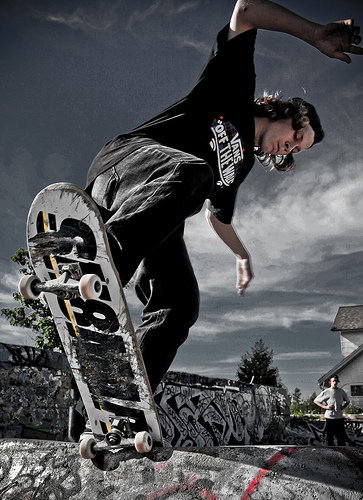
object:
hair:
[254, 87, 325, 173]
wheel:
[78, 273, 102, 299]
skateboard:
[18, 182, 166, 461]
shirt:
[313, 387, 350, 419]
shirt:
[83, 39, 256, 225]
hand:
[235, 255, 252, 296]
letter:
[60, 340, 130, 374]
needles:
[249, 346, 273, 358]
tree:
[237, 335, 296, 387]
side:
[8, 362, 280, 451]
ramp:
[15, 401, 361, 487]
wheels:
[19, 275, 42, 300]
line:
[247, 442, 283, 494]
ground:
[0, 437, 363, 488]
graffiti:
[166, 382, 274, 439]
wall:
[24, 340, 329, 446]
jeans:
[325, 418, 347, 448]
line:
[57, 287, 91, 350]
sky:
[17, 21, 201, 111]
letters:
[209, 120, 244, 188]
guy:
[82, 0, 363, 435]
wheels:
[79, 437, 97, 460]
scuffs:
[53, 320, 107, 370]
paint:
[256, 454, 298, 490]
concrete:
[86, 426, 336, 499]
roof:
[329, 304, 361, 331]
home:
[316, 305, 358, 429]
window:
[350, 385, 362, 397]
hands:
[326, 405, 335, 411]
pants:
[325, 417, 347, 448]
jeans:
[80, 135, 208, 399]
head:
[255, 90, 325, 173]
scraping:
[66, 337, 137, 405]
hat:
[289, 97, 325, 145]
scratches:
[68, 330, 129, 397]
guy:
[313, 374, 350, 447]